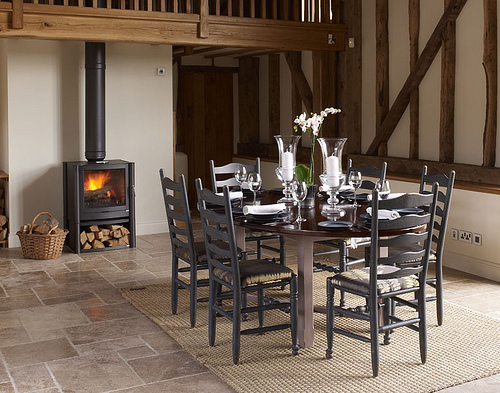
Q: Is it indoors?
A: Yes, it is indoors.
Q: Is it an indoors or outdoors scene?
A: It is indoors.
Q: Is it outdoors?
A: No, it is indoors.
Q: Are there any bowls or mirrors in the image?
A: No, there are no mirrors or bowls.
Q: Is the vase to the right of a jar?
A: No, the vase is to the right of a chair.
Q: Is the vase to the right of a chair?
A: No, the vase is to the left of a chair.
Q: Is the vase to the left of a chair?
A: Yes, the vase is to the left of a chair.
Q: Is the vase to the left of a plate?
A: No, the vase is to the left of a chair.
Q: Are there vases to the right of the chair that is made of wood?
A: Yes, there is a vase to the right of the chair.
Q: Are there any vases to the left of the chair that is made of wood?
A: No, the vase is to the right of the chair.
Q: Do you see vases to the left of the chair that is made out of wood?
A: No, the vase is to the right of the chair.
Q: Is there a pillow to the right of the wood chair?
A: No, there is a vase to the right of the chair.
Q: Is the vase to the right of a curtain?
A: No, the vase is to the right of a chair.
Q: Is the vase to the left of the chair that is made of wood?
A: No, the vase is to the right of the chair.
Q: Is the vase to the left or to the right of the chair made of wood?
A: The vase is to the right of the chair.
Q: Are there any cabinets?
A: No, there are no cabinets.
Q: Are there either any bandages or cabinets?
A: No, there are no cabinets or bandages.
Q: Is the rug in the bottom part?
A: Yes, the rug is in the bottom of the image.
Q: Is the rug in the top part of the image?
A: No, the rug is in the bottom of the image.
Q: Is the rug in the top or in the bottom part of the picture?
A: The rug is in the bottom of the image.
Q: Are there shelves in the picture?
A: No, there are no shelves.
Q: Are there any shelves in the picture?
A: No, there are no shelves.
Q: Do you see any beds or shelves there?
A: No, there are no shelves or beds.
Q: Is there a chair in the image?
A: Yes, there is a chair.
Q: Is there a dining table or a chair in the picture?
A: Yes, there is a chair.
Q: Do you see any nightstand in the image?
A: No, there are no nightstands.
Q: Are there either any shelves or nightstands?
A: No, there are no nightstands or shelves.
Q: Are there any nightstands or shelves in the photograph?
A: No, there are no nightstands or shelves.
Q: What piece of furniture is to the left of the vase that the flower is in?
A: The piece of furniture is a chair.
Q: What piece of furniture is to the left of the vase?
A: The piece of furniture is a chair.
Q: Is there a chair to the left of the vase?
A: Yes, there is a chair to the left of the vase.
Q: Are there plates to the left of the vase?
A: No, there is a chair to the left of the vase.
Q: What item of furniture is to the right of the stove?
A: The piece of furniture is a chair.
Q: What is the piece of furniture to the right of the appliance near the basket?
A: The piece of furniture is a chair.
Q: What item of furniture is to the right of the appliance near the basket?
A: The piece of furniture is a chair.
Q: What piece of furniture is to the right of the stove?
A: The piece of furniture is a chair.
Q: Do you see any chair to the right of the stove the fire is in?
A: Yes, there is a chair to the right of the stove.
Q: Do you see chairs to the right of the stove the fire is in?
A: Yes, there is a chair to the right of the stove.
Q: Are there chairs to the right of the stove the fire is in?
A: Yes, there is a chair to the right of the stove.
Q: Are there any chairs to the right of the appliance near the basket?
A: Yes, there is a chair to the right of the stove.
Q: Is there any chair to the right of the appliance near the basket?
A: Yes, there is a chair to the right of the stove.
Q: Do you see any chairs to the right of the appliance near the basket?
A: Yes, there is a chair to the right of the stove.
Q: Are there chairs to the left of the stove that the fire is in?
A: No, the chair is to the right of the stove.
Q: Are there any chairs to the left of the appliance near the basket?
A: No, the chair is to the right of the stove.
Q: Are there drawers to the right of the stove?
A: No, there is a chair to the right of the stove.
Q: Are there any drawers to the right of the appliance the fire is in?
A: No, there is a chair to the right of the stove.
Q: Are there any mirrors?
A: No, there are no mirrors.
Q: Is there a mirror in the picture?
A: No, there are no mirrors.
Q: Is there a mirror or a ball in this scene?
A: No, there are no mirrors or balls.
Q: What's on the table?
A: The glass is on the table.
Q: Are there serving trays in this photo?
A: No, there are no serving trays.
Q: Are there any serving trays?
A: No, there are no serving trays.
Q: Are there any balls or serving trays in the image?
A: No, there are no serving trays or balls.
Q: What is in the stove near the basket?
A: The fire is in the stove.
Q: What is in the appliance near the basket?
A: The fire is in the stove.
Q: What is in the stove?
A: The fire is in the stove.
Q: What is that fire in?
A: The fire is in the stove.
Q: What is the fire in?
A: The fire is in the stove.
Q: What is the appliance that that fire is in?
A: The appliance is a stove.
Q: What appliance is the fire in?
A: The fire is in the stove.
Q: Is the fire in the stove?
A: Yes, the fire is in the stove.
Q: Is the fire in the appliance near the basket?
A: Yes, the fire is in the stove.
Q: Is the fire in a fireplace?
A: No, the fire is in the stove.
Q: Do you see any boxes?
A: No, there are no boxes.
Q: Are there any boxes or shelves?
A: No, there are no boxes or shelves.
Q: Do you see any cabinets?
A: No, there are no cabinets.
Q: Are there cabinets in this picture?
A: No, there are no cabinets.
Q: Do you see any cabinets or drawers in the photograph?
A: No, there are no cabinets or drawers.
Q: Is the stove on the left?
A: Yes, the stove is on the left of the image.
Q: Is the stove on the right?
A: No, the stove is on the left of the image.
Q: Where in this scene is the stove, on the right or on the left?
A: The stove is on the left of the image.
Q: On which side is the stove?
A: The stove is on the left of the image.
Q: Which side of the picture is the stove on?
A: The stove is on the left of the image.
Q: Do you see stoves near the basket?
A: Yes, there is a stove near the basket.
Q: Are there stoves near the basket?
A: Yes, there is a stove near the basket.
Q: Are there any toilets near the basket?
A: No, there is a stove near the basket.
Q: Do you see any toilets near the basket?
A: No, there is a stove near the basket.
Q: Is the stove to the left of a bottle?
A: No, the stove is to the left of a chair.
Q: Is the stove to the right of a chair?
A: No, the stove is to the left of a chair.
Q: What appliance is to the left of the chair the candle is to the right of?
A: The appliance is a stove.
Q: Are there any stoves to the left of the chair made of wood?
A: Yes, there is a stove to the left of the chair.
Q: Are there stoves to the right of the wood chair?
A: No, the stove is to the left of the chair.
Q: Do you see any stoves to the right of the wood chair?
A: No, the stove is to the left of the chair.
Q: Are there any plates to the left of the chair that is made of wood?
A: No, there is a stove to the left of the chair.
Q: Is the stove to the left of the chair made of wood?
A: Yes, the stove is to the left of the chair.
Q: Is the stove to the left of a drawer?
A: No, the stove is to the left of the chair.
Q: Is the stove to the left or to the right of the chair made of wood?
A: The stove is to the left of the chair.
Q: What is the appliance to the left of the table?
A: The appliance is a stove.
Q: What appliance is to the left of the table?
A: The appliance is a stove.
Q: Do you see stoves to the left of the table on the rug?
A: Yes, there is a stove to the left of the table.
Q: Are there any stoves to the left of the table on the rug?
A: Yes, there is a stove to the left of the table.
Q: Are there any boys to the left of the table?
A: No, there is a stove to the left of the table.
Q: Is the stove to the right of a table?
A: No, the stove is to the left of a table.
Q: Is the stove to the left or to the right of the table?
A: The stove is to the left of the table.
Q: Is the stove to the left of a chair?
A: Yes, the stove is to the left of a chair.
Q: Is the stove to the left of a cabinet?
A: No, the stove is to the left of a chair.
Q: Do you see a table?
A: Yes, there is a table.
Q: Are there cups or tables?
A: Yes, there is a table.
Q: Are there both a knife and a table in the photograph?
A: No, there is a table but no knives.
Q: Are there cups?
A: No, there are no cups.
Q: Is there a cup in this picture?
A: No, there are no cups.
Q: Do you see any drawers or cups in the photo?
A: No, there are no cups or drawers.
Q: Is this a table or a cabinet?
A: This is a table.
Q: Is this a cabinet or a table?
A: This is a table.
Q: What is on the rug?
A: The table is on the rug.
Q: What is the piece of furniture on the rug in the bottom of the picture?
A: The piece of furniture is a table.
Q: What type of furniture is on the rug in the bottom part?
A: The piece of furniture is a table.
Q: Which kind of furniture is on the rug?
A: The piece of furniture is a table.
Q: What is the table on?
A: The table is on the rug.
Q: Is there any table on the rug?
A: Yes, there is a table on the rug.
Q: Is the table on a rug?
A: Yes, the table is on a rug.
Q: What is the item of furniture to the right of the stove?
A: The piece of furniture is a table.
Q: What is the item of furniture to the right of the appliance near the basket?
A: The piece of furniture is a table.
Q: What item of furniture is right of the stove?
A: The piece of furniture is a table.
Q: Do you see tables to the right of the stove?
A: Yes, there is a table to the right of the stove.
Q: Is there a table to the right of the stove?
A: Yes, there is a table to the right of the stove.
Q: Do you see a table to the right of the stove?
A: Yes, there is a table to the right of the stove.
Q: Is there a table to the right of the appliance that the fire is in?
A: Yes, there is a table to the right of the stove.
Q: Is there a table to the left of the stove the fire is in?
A: No, the table is to the right of the stove.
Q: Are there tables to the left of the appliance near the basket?
A: No, the table is to the right of the stove.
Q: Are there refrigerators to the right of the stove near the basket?
A: No, there is a table to the right of the stove.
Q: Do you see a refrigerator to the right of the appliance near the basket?
A: No, there is a table to the right of the stove.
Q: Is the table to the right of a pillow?
A: No, the table is to the right of the stove.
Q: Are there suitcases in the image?
A: No, there are no suitcases.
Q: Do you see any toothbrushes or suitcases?
A: No, there are no suitcases or toothbrushes.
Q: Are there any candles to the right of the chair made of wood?
A: Yes, there is a candle to the right of the chair.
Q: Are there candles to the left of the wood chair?
A: No, the candle is to the right of the chair.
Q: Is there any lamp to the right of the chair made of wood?
A: No, there is a candle to the right of the chair.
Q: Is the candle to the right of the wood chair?
A: Yes, the candle is to the right of the chair.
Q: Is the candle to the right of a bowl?
A: No, the candle is to the right of the chair.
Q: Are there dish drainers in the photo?
A: No, there are no dish drainers.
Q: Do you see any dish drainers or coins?
A: No, there are no dish drainers or coins.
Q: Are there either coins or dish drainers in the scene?
A: No, there are no dish drainers or coins.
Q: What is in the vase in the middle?
A: The flower is in the vase.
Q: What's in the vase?
A: The flower is in the vase.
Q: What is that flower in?
A: The flower is in the vase.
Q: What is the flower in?
A: The flower is in the vase.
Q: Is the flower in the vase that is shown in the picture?
A: Yes, the flower is in the vase.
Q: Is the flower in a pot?
A: No, the flower is in the vase.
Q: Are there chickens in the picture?
A: No, there are no chickens.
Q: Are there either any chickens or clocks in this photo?
A: No, there are no chickens or clocks.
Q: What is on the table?
A: The glass is on the table.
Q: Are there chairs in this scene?
A: Yes, there is a chair.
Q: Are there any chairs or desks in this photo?
A: Yes, there is a chair.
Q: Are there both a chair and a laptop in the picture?
A: No, there is a chair but no laptops.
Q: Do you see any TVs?
A: No, there are no tvs.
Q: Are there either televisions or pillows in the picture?
A: No, there are no televisions or pillows.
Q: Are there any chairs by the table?
A: Yes, there is a chair by the table.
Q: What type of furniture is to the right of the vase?
A: The piece of furniture is a chair.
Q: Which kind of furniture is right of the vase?
A: The piece of furniture is a chair.